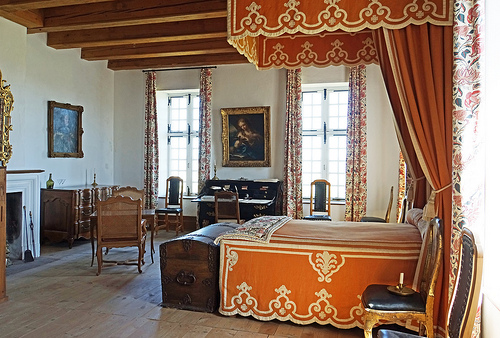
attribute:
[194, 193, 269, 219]
wooden desk — brown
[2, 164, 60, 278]
fireplace — white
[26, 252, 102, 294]
floors — are wooden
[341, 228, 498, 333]
chair — is wooden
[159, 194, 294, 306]
trunk — is wooden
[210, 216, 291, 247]
blanket — is floral patterned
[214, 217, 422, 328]
beadspread — is orange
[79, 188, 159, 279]
chair — brown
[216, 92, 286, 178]
picture — square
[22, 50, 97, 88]
wall — white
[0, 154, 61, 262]
fireplace — white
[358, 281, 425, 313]
seat — black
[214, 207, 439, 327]
bedspread — orange, is cream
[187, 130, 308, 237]
desk — black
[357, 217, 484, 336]
chair — wooden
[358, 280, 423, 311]
cushion — black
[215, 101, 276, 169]
frame — fancy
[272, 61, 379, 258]
windows — long